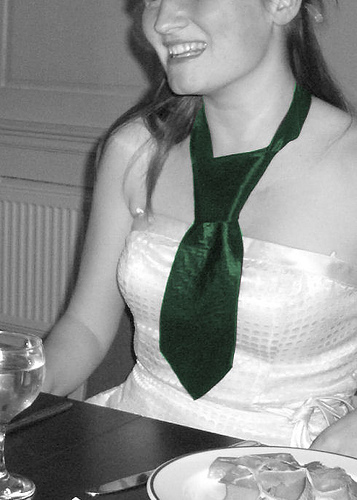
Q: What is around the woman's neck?
A: A tie.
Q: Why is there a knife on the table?
A: To cut the food.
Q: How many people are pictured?
A: One.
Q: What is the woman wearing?
A: A dress.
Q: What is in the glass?
A: Water.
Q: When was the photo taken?
A: During a meal.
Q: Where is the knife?
A: On the table.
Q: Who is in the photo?
A: The woman.